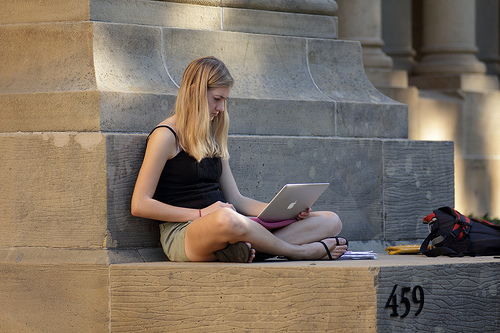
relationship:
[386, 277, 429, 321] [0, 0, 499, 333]
number on background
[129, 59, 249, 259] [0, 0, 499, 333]
woman sits next to background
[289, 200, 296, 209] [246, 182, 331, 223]
apple on computer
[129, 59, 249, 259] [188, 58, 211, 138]
woman has hair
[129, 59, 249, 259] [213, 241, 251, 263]
woman wears flip flop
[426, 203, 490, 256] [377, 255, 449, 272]
backpack on floor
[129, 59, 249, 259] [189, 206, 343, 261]
girl with crossed leg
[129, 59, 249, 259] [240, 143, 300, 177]
girl leans on wall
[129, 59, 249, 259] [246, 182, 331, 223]
woman studying on computer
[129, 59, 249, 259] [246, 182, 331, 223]
lady studying on computer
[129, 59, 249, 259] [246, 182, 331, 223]
person studying on computer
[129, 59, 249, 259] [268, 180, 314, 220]
female studying on computer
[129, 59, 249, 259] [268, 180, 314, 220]
woman sitting with computer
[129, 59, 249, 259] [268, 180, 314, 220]
lady sitting with computer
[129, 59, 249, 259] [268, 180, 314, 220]
female sitting with computer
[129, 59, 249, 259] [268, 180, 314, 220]
person sitting with computer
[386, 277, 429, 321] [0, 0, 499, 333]
number showing on background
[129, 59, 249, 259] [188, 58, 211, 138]
lady with hair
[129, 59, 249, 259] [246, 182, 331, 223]
woman working on computer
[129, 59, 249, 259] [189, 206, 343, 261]
woman with crossed leg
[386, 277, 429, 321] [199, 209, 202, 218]
number on band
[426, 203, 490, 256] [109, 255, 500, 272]
backpack laying on floor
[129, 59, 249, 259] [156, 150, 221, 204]
woman wearing top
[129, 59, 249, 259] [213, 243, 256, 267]
woman wearing sandal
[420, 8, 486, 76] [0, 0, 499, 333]
pedestal of a background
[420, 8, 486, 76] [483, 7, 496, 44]
column in background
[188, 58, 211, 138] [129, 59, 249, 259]
hair on head of woman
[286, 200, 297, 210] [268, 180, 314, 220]
apple on computer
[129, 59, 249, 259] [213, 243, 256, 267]
woman wearing flip flop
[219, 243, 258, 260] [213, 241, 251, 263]
foot in flip flop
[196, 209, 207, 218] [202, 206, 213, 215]
band on wrist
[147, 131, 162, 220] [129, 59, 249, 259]
arm of woman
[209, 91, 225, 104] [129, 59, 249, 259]
eye of person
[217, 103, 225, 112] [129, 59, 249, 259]
nose of person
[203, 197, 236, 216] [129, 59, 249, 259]
hand of person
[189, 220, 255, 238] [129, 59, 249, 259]
leg of person